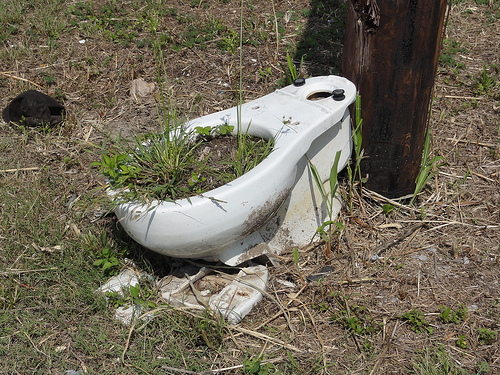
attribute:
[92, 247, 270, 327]
toilet seat — broken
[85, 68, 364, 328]
toilet bowl — broken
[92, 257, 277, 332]
pieces — cracked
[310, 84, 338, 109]
hole — small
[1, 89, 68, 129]
rock — black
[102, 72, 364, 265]
toilet bowl — broken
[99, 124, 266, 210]
weeds — growing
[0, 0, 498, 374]
grass — brown, dried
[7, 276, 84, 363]
grass — dead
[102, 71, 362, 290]
toilet bowl — broken, white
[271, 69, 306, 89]
toilet knob — black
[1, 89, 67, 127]
black item — fabric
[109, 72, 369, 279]
toilet bowl — white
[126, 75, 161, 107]
rock — white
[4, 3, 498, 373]
dirt — brown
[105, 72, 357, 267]
toilet seat — broken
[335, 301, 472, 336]
grassy patches — brown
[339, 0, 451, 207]
pole — brown, wooden, utility pole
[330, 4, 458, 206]
pole — brown, wooden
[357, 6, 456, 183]
telephone pole — dark, brown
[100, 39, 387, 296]
toilet — broken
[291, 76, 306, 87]
bolt — black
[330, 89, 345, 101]
bolt — black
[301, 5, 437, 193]
pole — brown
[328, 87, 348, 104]
screw — black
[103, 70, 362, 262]
toilet — broken, white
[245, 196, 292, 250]
dirt — brown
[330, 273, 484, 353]
grass — green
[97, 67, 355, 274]
toilet bowl — white